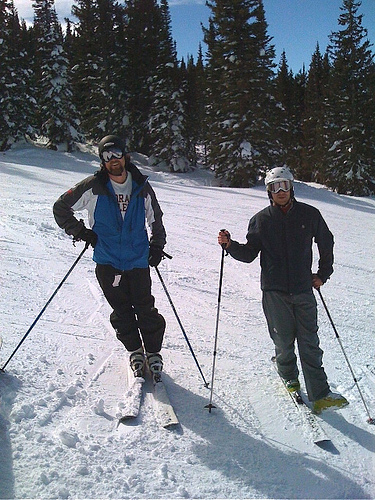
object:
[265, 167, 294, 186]
helmet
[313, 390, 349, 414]
boots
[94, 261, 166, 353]
pants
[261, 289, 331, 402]
pants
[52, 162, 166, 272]
jacket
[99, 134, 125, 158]
helmet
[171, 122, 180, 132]
snow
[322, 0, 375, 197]
trees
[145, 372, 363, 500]
shadow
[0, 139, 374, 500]
ground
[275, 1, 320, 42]
sky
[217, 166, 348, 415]
man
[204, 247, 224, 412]
pole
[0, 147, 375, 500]
snow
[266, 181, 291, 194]
goggles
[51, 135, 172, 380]
man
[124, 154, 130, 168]
hair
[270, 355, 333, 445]
skis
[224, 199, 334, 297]
jacket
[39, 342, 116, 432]
tracks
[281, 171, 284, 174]
holes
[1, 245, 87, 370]
pole